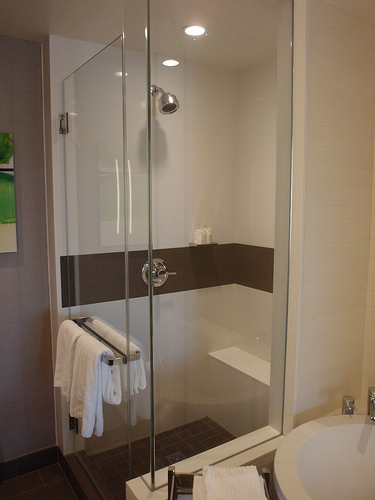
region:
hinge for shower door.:
[57, 112, 67, 140]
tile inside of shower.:
[185, 427, 210, 447]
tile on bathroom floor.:
[29, 465, 42, 486]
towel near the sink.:
[210, 474, 247, 498]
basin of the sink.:
[322, 468, 361, 495]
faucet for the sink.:
[369, 387, 373, 411]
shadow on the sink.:
[357, 430, 371, 453]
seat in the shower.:
[227, 352, 263, 377]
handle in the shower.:
[155, 260, 175, 285]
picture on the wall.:
[1, 174, 11, 254]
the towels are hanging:
[55, 320, 120, 436]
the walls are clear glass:
[59, 0, 294, 499]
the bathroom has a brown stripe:
[61, 242, 274, 306]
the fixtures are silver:
[141, 84, 179, 290]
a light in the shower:
[162, 22, 204, 67]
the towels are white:
[52, 320, 120, 442]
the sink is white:
[272, 414, 371, 497]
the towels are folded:
[191, 463, 266, 498]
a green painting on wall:
[0, 131, 18, 254]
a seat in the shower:
[204, 346, 269, 441]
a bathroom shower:
[40, 17, 373, 468]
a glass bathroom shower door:
[20, 27, 307, 494]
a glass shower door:
[14, 53, 301, 496]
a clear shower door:
[41, 52, 299, 491]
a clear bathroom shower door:
[32, 46, 361, 484]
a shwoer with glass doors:
[30, 33, 291, 491]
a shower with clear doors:
[10, 22, 290, 493]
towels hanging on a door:
[40, 295, 228, 468]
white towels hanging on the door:
[39, 299, 193, 461]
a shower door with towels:
[39, 293, 231, 454]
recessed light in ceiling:
[186, 23, 205, 36]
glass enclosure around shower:
[62, 2, 288, 493]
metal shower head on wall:
[151, 83, 178, 112]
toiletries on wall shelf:
[189, 224, 216, 248]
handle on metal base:
[142, 256, 177, 286]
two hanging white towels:
[52, 318, 120, 436]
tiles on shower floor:
[91, 413, 234, 497]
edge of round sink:
[275, 413, 373, 497]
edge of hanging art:
[1, 131, 18, 253]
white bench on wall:
[209, 345, 272, 386]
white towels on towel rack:
[45, 303, 139, 465]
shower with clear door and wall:
[46, 18, 280, 496]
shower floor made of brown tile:
[80, 408, 262, 496]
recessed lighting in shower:
[106, 9, 309, 158]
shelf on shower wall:
[173, 153, 260, 305]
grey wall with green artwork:
[0, 42, 43, 466]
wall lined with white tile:
[302, 4, 373, 429]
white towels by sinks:
[182, 391, 373, 498]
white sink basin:
[275, 397, 373, 498]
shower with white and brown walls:
[54, 45, 263, 478]